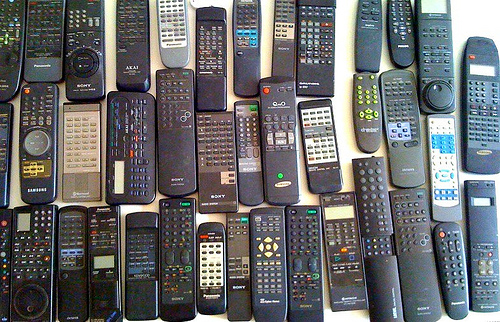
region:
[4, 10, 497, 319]
a group of many remote control units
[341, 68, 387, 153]
this remote has chartreuse colored buttons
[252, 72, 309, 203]
there is a red button in the corner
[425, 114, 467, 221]
there is blue areas on this remote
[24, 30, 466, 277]
there are remotes of various shapes and sizes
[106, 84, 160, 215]
this could be a blackberry...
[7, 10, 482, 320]
i have never seen so many different remotes!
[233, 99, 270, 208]
this remote is very narrow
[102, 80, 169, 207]
so many buttons, so little time...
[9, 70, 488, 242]
there are a lot of red buttons.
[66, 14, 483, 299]
assorted remote controls on white table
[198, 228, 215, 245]
red rectangle button on remote control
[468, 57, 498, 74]
screen on remote control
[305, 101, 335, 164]
white face under buttons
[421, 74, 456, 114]
round dial on bottom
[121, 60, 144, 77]
logo in white on bottom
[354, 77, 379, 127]
neon green buttons on remote control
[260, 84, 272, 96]
round red button on top left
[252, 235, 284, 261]
yellow arrow buttons in middle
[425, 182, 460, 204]
blue block under white buttons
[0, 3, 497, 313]
Cell phones and remote controls on a surface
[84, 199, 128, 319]
Cell phone is black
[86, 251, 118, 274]
Screen of cell phone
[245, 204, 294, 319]
Remote control is black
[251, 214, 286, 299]
Keypads of remote control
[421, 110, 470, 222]
Remote control is grey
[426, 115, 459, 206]
Key pads are on a white and blue surface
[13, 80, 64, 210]
Blue remote control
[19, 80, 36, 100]
red button of remote control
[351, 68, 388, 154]
Remote control with green keys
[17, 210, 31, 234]
This is a gray panel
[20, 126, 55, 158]
this is a large gray button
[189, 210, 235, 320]
this is a small remote control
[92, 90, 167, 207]
this is a landscape remote control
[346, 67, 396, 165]
small remote with green buttons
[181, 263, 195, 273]
a small green button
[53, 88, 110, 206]
silver and white remote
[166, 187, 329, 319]
A group of five remotes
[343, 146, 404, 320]
a long remote control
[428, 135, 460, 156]
a light blue panel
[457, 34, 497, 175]
a television remote device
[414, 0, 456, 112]
a television remote device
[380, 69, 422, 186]
a television remote device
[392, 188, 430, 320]
a television remote device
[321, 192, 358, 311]
a television remote device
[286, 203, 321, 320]
a television remote device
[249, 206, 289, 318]
a television remote device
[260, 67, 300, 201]
a television remote device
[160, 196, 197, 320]
a television remote device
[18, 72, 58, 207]
a television remote device